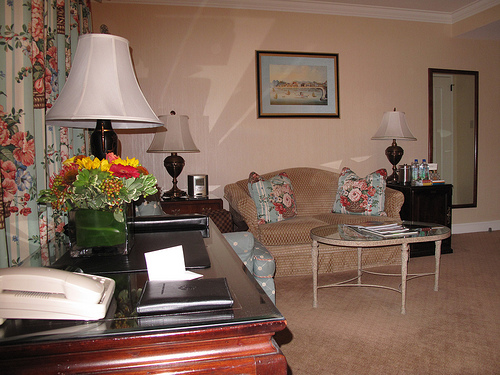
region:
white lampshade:
[45, 30, 162, 132]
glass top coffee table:
[309, 222, 450, 307]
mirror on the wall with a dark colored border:
[429, 68, 479, 207]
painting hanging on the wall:
[256, 50, 341, 120]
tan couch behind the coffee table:
[222, 168, 406, 278]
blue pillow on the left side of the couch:
[248, 173, 295, 224]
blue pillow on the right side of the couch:
[330, 168, 387, 215]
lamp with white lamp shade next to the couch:
[369, 107, 416, 187]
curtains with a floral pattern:
[0, 2, 100, 269]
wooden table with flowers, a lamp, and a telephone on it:
[0, 214, 295, 373]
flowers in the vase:
[47, 159, 148, 250]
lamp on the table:
[153, 108, 198, 199]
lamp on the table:
[372, 88, 412, 183]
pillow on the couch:
[331, 169, 386, 214]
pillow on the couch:
[249, 172, 302, 213]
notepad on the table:
[138, 274, 233, 315]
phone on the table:
[1, 262, 128, 327]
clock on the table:
[183, 173, 208, 201]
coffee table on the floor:
[291, 205, 451, 326]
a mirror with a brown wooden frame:
[426, 68, 478, 210]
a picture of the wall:
[252, 51, 339, 118]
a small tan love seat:
[222, 164, 408, 278]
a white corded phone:
[3, 260, 114, 325]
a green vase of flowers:
[37, 153, 157, 255]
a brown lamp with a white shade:
[43, 32, 165, 157]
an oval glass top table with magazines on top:
[308, 222, 450, 313]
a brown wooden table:
[0, 212, 291, 372]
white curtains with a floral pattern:
[0, 0, 90, 284]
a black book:
[136, 274, 235, 311]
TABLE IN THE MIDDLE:
[314, 220, 457, 310]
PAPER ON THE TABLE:
[361, 217, 404, 244]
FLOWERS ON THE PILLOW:
[343, 180, 370, 209]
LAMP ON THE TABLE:
[382, 107, 417, 158]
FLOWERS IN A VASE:
[73, 161, 124, 206]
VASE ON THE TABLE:
[97, 215, 135, 282]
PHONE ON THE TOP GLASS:
[0, 265, 100, 319]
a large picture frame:
[251, 45, 341, 120]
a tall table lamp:
[371, 105, 416, 180]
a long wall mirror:
[423, 65, 489, 207]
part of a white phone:
[1, 260, 116, 322]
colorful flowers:
[38, 148, 156, 214]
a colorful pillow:
[247, 171, 299, 221]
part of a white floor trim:
[453, 218, 498, 238]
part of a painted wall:
[256, 17, 403, 49]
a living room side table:
[401, 181, 459, 255]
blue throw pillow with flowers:
[248, 169, 298, 224]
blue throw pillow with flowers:
[331, 165, 389, 215]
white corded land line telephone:
[1, 266, 116, 321]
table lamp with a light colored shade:
[146, 109, 198, 199]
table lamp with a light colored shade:
[42, 32, 162, 157]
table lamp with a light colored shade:
[370, 108, 417, 183]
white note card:
[143, 244, 203, 281]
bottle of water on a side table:
[410, 158, 419, 182]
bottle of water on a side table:
[419, 158, 428, 179]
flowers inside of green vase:
[39, 150, 159, 250]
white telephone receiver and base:
[0, 264, 115, 322]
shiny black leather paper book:
[135, 276, 235, 315]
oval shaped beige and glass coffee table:
[310, 219, 451, 314]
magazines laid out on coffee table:
[342, 215, 418, 238]